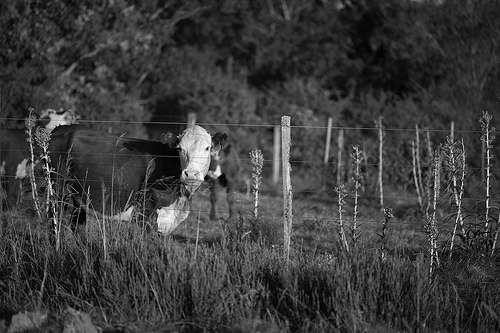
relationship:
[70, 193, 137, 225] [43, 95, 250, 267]
belly a cow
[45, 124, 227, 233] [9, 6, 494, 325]
cow in photo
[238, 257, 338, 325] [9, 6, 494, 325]
grass in photo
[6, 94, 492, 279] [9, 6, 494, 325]
fence in photo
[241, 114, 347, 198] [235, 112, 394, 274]
wire on fence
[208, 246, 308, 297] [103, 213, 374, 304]
grass in field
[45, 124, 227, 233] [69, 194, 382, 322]
cow in field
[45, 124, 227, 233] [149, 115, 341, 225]
cow behind fence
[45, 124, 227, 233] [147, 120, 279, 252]
cow behind fence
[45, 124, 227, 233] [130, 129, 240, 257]
cow behind fence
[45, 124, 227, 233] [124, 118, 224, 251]
cow behind fence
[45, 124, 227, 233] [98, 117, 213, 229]
cow behind fence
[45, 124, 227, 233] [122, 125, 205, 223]
cow behind fence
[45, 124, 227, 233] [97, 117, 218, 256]
cow behind fence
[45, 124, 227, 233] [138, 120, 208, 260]
cow behind fence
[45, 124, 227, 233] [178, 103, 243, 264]
cow behind fence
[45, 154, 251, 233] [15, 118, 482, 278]
cow behind fence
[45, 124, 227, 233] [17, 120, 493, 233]
cow behind fence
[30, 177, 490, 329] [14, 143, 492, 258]
grass near fence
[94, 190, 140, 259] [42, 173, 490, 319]
plants out of grass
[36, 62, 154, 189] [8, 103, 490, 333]
trees behind field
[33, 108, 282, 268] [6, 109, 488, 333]
wires on fence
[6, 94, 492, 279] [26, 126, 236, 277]
fence keep cow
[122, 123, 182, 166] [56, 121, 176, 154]
shadow on back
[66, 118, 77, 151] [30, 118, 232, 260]
bone of cow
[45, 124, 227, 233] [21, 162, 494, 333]
cow in field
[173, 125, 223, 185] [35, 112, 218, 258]
face of cow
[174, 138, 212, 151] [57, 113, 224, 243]
eyes of cow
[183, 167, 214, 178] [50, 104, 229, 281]
nose of cow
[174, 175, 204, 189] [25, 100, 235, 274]
mouth of cow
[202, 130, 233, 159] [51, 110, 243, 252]
ear of cow